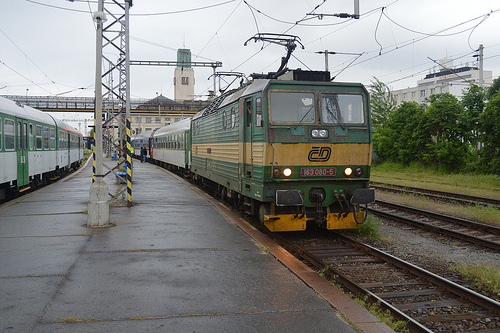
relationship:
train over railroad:
[133, 69, 373, 234] [256, 178, 499, 325]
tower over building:
[172, 48, 197, 103] [133, 95, 216, 135]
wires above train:
[239, 1, 499, 62] [133, 69, 373, 234]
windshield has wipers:
[266, 89, 370, 128] [295, 99, 343, 125]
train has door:
[133, 69, 373, 234] [241, 96, 255, 175]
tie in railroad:
[370, 288, 447, 299] [311, 245, 499, 324]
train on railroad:
[133, 69, 373, 234] [311, 245, 499, 324]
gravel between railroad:
[400, 234, 499, 263] [311, 245, 499, 324]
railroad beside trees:
[311, 245, 499, 324] [367, 77, 499, 178]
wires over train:
[239, 1, 499, 62] [133, 69, 373, 234]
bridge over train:
[3, 95, 214, 116] [133, 69, 373, 234]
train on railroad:
[133, 69, 373, 234] [256, 178, 499, 325]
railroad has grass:
[256, 178, 499, 325] [454, 260, 496, 300]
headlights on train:
[275, 167, 362, 178] [133, 69, 373, 234]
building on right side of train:
[369, 47, 497, 110] [170, 70, 372, 229]